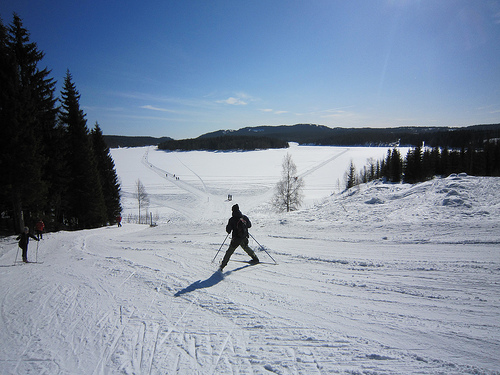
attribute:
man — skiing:
[206, 185, 257, 297]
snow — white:
[76, 278, 493, 356]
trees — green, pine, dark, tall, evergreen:
[18, 85, 120, 236]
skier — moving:
[210, 198, 269, 272]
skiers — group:
[19, 217, 283, 281]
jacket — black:
[230, 217, 252, 229]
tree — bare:
[275, 138, 324, 223]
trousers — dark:
[231, 238, 256, 263]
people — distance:
[149, 161, 204, 200]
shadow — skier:
[188, 262, 245, 312]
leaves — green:
[78, 160, 103, 196]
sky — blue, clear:
[54, 8, 436, 127]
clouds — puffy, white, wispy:
[131, 87, 310, 119]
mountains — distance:
[147, 120, 450, 140]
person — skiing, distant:
[12, 218, 54, 275]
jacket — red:
[35, 222, 48, 231]